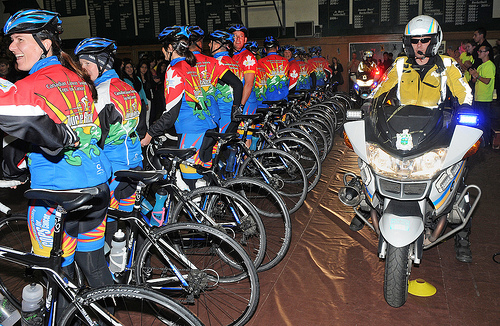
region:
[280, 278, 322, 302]
this is the ground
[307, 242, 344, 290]
the ground is wrinkled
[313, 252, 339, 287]
the ground is grey in color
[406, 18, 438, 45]
this is a helmet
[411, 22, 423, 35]
the helmet is white in color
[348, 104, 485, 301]
this is a motorcycle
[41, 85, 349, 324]
these are some bicycles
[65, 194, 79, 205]
the seat is black in color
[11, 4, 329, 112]
these are some people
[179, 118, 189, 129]
the jacket is blue in color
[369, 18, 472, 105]
this is a man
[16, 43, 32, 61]
the man is light skinned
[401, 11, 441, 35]
this is a helmet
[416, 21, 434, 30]
the helmet is white in color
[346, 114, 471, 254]
this is a motorbike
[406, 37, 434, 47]
this is a spectacle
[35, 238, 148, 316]
this is a bicycle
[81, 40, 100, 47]
the helmet is blue in color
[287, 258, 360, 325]
this isthe floor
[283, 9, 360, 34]
this is the wall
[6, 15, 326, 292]
line of bikers at rally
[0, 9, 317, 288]
group of people lined up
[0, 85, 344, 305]
group of bikes lined up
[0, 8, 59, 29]
blue and black biking helmet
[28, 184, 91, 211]
black seat on bike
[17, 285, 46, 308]
white plastic water bottle in bike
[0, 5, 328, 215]
group of people wearing the same clothes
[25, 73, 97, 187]
red and blue jersey on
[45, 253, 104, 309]
black leggings on pants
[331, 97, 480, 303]
white motorcycle in background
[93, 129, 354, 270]
the bikes are black in color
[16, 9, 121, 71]
the helmets are the same in color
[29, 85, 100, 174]
the blouse is ble and red in color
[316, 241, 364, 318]
the floor is brown in color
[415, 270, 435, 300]
the oplate is yellow in color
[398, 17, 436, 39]
the helmet is white in color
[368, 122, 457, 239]
the motor bike is white in color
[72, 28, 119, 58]
the helmet is blue in color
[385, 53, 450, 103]
the jacket is red in color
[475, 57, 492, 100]
the shirt is yellow in color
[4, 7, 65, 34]
helmet on the biker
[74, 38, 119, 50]
helmet on the cyclist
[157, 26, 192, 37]
helmet on the cyclist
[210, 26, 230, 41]
helmet on the cyclist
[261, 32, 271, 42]
helmet on the cyclist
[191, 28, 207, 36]
helmet on the cyclist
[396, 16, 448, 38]
helmet on the biker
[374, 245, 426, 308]
tire on the motorcycle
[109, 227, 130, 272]
water bottle on the bike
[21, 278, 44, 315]
water bottle on the bike